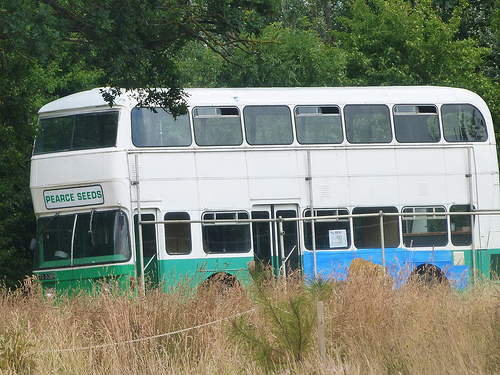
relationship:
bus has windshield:
[31, 87, 500, 306] [32, 213, 128, 265]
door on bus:
[136, 209, 159, 307] [31, 87, 500, 306]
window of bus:
[162, 211, 192, 259] [31, 87, 500, 306]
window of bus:
[203, 211, 251, 254] [31, 87, 500, 306]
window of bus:
[303, 208, 351, 250] [31, 87, 500, 306]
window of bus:
[352, 205, 399, 250] [31, 87, 500, 306]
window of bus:
[403, 205, 447, 247] [31, 87, 500, 306]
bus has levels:
[31, 87, 500, 306] [36, 87, 494, 219]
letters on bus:
[43, 184, 104, 210] [31, 87, 500, 306]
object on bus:
[331, 229, 346, 249] [31, 87, 500, 306]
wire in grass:
[15, 303, 272, 353] [2, 277, 498, 373]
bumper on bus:
[32, 268, 138, 304] [31, 87, 500, 306]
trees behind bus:
[27, 1, 497, 89] [31, 87, 500, 306]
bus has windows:
[31, 87, 500, 306] [305, 203, 473, 252]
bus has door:
[31, 87, 500, 306] [252, 204, 300, 293]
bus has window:
[31, 87, 500, 306] [203, 211, 251, 254]